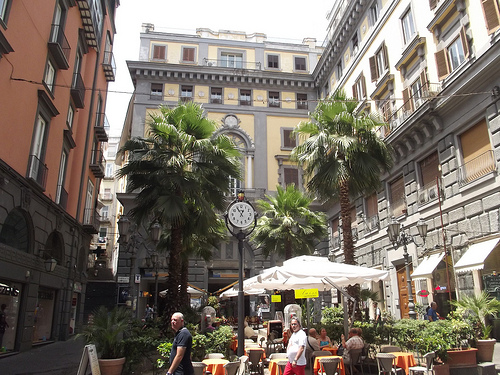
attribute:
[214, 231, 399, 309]
umbrella — white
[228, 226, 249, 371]
pole — metal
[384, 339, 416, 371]
cloths — orange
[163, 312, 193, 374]
pedestrian — walking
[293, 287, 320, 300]
sign — yellow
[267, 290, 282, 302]
sign — yellow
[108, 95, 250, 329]
tree — green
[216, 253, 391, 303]
white umbrella — large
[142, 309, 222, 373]
man — walking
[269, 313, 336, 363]
woman — walking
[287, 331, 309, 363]
shirt — white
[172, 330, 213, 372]
shirt — black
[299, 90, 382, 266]
tree — palm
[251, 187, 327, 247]
tree — palm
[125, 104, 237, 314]
tree — palm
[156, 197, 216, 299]
tree — palm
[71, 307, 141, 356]
plant — bushy, green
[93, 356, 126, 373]
pot — brown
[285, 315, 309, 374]
pedestrian — walking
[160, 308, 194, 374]
pedestrian — walking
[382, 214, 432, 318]
post — black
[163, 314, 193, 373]
person — sitting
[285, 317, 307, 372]
person — sitting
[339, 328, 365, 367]
person — sitting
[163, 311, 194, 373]
man — walking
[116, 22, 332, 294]
building — large, grey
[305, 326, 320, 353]
person — sitting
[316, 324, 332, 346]
person — sitting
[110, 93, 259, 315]
tree — tall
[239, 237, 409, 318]
umbrella — white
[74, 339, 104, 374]
sign — sitting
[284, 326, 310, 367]
shirt — white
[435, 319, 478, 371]
plant — large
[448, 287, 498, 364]
plant — large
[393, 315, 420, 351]
plant — large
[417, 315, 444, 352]
plant — large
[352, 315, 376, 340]
plant — large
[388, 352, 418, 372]
tablecloth — orange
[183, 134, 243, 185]
leaves — large, green